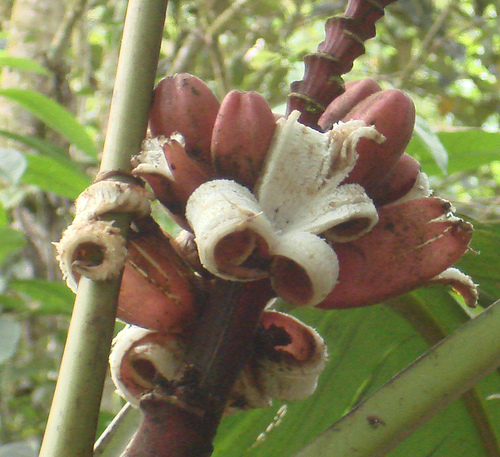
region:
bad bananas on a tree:
[65, 2, 469, 454]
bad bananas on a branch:
[47, 15, 490, 442]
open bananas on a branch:
[72, 53, 409, 455]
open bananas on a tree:
[82, 13, 469, 455]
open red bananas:
[77, 46, 454, 452]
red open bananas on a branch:
[29, 47, 499, 449]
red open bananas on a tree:
[73, 25, 460, 450]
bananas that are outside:
[39, 36, 441, 452]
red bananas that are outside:
[39, 42, 472, 455]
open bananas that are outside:
[29, 38, 475, 425]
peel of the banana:
[194, 184, 272, 274]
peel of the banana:
[273, 233, 333, 304]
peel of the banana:
[323, 227, 450, 300]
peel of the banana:
[56, 197, 121, 272]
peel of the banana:
[105, 322, 177, 391]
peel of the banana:
[252, 322, 304, 402]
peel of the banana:
[138, 147, 203, 195]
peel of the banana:
[226, 382, 263, 417]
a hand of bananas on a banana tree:
[52, 61, 480, 424]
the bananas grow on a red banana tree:
[71, 70, 473, 430]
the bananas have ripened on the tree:
[190, 122, 480, 406]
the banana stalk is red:
[273, 3, 388, 126]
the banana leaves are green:
[98, 127, 497, 452]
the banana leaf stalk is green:
[23, 252, 496, 443]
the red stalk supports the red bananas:
[100, 282, 284, 455]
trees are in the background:
[16, 7, 497, 309]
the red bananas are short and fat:
[294, 76, 419, 220]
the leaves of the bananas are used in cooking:
[269, 303, 489, 453]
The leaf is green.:
[4, 88, 103, 162]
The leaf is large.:
[6, 85, 96, 160]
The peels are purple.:
[78, 78, 466, 413]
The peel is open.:
[207, 98, 354, 300]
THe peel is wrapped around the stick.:
[44, 165, 214, 335]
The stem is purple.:
[115, 6, 369, 456]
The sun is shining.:
[1, 2, 498, 448]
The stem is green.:
[276, 299, 493, 454]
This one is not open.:
[322, 78, 417, 209]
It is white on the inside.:
[179, 110, 360, 291]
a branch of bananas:
[58, 35, 498, 384]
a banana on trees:
[55, 2, 496, 454]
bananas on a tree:
[50, 34, 490, 456]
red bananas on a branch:
[57, 30, 462, 435]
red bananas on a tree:
[50, 36, 495, 452]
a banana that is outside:
[4, 22, 449, 455]